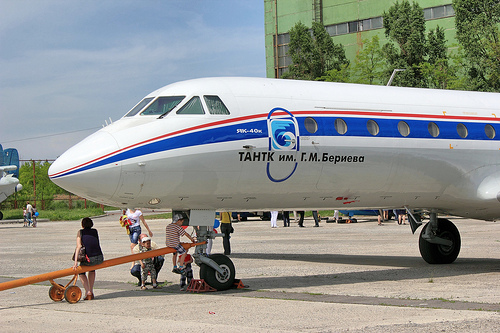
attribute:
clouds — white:
[2, 4, 270, 146]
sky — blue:
[0, 0, 267, 167]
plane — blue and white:
[30, 47, 471, 265]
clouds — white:
[89, 16, 221, 73]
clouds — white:
[0, 0, 268, 170]